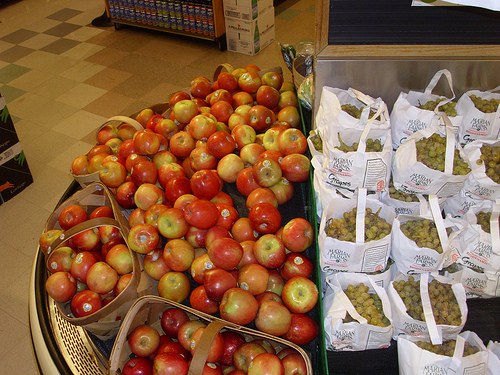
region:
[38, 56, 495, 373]
mixed produce display in grocery store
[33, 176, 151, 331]
yellow and red apples displayed in a wooden basket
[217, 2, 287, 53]
stacked boxes of sparkling water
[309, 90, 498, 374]
green grapes in white bags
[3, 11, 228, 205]
multi colored square tiles on floor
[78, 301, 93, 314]
produce sticker on apple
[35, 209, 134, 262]
wooden handle on woven basket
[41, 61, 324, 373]
produce display of apples for sale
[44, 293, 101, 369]
grate around apple display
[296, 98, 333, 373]
green divider between apples and grapes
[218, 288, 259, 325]
apple is next to apple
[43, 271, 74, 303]
apple is next to apple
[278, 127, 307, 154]
apple is next to apple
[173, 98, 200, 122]
apple is next to apple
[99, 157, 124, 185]
apple is next to apple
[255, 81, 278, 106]
apple is next to apple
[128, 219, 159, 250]
apple is next to apple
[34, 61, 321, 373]
apple is red and green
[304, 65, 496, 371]
grapes is in white bag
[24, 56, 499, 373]
fruits are on top of table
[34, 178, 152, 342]
apple is in brown basket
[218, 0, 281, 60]
white boxes on floor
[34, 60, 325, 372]
apple have stickers on them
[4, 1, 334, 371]
tile is square on the floor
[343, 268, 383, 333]
green grapes in the bag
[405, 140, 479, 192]
green grapes in the bag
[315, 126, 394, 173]
green grapes in the bag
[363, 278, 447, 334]
green grapes in the bag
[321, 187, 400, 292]
green grapes in the bag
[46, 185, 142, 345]
apples in the basket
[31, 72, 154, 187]
apples in the basket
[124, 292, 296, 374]
apples in the basket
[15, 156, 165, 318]
apples in the basket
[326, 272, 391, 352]
Green grapes in a bag.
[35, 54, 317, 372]
Apples on the table.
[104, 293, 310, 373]
Basket holding the apples.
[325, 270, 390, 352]
White bag holding the bag.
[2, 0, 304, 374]
Checkered tile floor.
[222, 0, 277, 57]
Boxes on the floor.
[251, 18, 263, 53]
Wine bottle on the box.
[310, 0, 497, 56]
Black display board above the grapes.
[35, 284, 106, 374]
Metal vent on the table.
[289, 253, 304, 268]
Sticker on the apple.